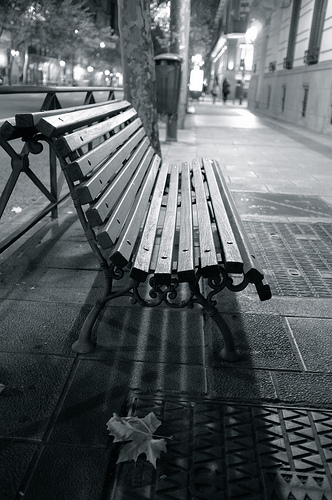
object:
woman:
[209, 74, 220, 100]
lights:
[10, 48, 21, 60]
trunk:
[116, 1, 161, 165]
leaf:
[107, 409, 174, 467]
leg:
[193, 293, 242, 363]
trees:
[12, 0, 43, 85]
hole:
[155, 379, 302, 478]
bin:
[155, 55, 184, 118]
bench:
[0, 96, 272, 371]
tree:
[115, 0, 160, 150]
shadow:
[28, 284, 287, 500]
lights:
[245, 20, 261, 43]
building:
[233, 0, 330, 138]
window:
[306, 0, 328, 61]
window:
[280, 1, 301, 67]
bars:
[282, 0, 296, 66]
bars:
[307, 0, 322, 63]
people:
[235, 77, 250, 105]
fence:
[0, 88, 116, 252]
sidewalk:
[2, 99, 331, 500]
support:
[133, 148, 273, 306]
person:
[219, 76, 232, 107]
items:
[159, 62, 173, 97]